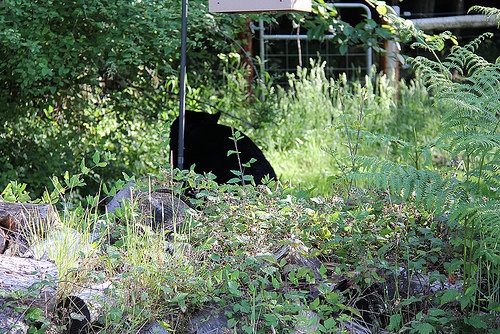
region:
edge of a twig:
[343, 308, 348, 315]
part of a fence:
[313, 94, 331, 122]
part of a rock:
[169, 240, 184, 254]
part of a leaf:
[363, 233, 373, 251]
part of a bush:
[97, 121, 132, 185]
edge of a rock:
[198, 291, 215, 313]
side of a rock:
[277, 288, 287, 301]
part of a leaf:
[414, 183, 421, 195]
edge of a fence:
[292, 68, 302, 92]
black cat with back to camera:
[186, 106, 274, 196]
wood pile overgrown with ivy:
[10, 197, 496, 332]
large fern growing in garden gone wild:
[360, 55, 497, 287]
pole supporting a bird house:
[175, 0, 313, 206]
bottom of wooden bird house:
[211, 0, 313, 15]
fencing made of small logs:
[391, 12, 497, 137]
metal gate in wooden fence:
[262, 0, 382, 107]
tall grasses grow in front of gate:
[279, 54, 414, 180]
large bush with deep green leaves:
[8, 1, 233, 188]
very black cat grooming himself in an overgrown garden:
[149, 108, 274, 212]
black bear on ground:
[169, 110, 276, 190]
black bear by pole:
[168, 111, 279, 190]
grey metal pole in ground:
[178, 0, 188, 170]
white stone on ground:
[111, 189, 200, 236]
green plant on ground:
[401, 28, 498, 103]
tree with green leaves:
[1, 2, 236, 112]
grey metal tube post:
[385, 5, 496, 115]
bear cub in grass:
[169, 108, 281, 191]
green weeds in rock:
[189, 200, 498, 332]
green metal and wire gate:
[256, 8, 373, 91]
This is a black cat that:
[166, 102, 260, 249]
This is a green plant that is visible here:
[388, 137, 425, 221]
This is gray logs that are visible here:
[14, 249, 51, 329]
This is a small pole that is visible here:
[176, 85, 200, 180]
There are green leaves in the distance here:
[70, 104, 99, 181]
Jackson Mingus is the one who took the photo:
[103, 28, 375, 305]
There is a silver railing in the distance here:
[426, 8, 453, 57]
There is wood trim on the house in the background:
[228, 28, 257, 98]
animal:
[137, 94, 256, 173]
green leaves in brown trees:
[23, 25, 63, 60]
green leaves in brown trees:
[89, 32, 130, 64]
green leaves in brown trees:
[145, 12, 192, 63]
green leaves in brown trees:
[27, 53, 73, 128]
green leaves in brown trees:
[114, 87, 153, 126]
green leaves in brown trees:
[295, 99, 322, 131]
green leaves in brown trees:
[329, 35, 353, 60]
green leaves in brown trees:
[358, 20, 411, 59]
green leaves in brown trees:
[411, 18, 453, 61]